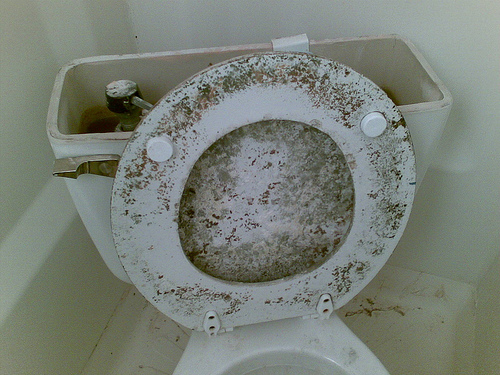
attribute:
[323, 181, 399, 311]
dots — brown 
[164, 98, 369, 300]
grime — brown , gray 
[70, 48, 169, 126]
cap — black 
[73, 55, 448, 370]
toilet — dirty 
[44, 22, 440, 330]
toilet — dirty , white 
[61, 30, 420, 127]
tank — TOILET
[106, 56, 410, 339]
seat — TOILET, ROUND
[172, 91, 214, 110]
stains — DIRT